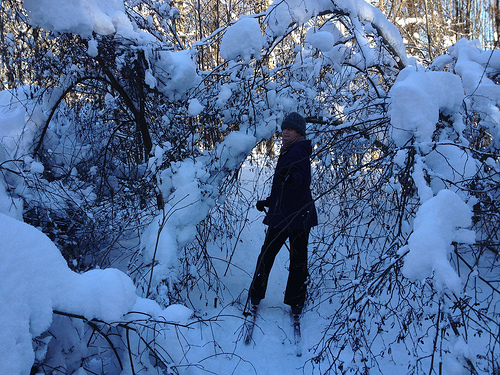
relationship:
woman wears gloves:
[244, 109, 313, 314] [257, 171, 295, 215]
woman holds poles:
[244, 109, 313, 314] [255, 166, 294, 284]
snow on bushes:
[4, 229, 193, 325] [5, 158, 164, 260]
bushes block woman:
[5, 158, 164, 260] [244, 109, 313, 314]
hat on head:
[280, 113, 308, 135] [281, 124, 299, 143]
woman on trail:
[244, 109, 313, 314] [226, 158, 322, 373]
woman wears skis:
[244, 109, 313, 314] [243, 292, 302, 356]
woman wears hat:
[244, 109, 313, 314] [280, 113, 308, 135]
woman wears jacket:
[244, 109, 313, 314] [261, 147, 318, 229]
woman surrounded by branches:
[244, 109, 313, 314] [11, 48, 157, 173]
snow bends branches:
[4, 229, 193, 325] [11, 48, 157, 173]